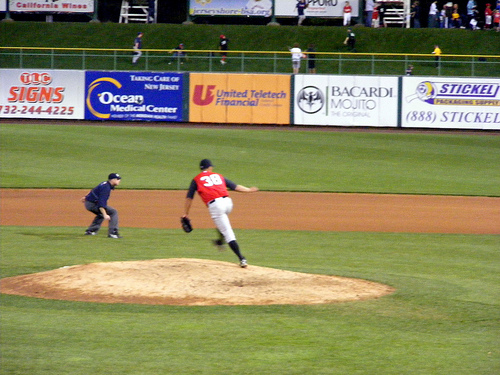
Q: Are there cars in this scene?
A: No, there are no cars.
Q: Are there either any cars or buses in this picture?
A: No, there are no cars or buses.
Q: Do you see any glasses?
A: No, there are no glasses.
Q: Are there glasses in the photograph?
A: No, there are no glasses.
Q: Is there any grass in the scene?
A: Yes, there is grass.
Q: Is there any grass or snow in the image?
A: Yes, there is grass.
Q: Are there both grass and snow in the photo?
A: No, there is grass but no snow.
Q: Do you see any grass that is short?
A: Yes, there is short grass.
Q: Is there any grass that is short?
A: Yes, there is grass that is short.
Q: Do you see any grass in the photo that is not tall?
A: Yes, there is short grass.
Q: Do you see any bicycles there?
A: No, there are no bicycles.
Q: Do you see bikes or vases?
A: No, there are no bikes or vases.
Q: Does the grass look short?
A: Yes, the grass is short.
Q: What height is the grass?
A: The grass is short.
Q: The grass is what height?
A: The grass is short.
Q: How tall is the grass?
A: The grass is short.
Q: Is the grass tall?
A: No, the grass is short.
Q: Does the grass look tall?
A: No, the grass is short.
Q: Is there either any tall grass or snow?
A: No, there is grass but it is short.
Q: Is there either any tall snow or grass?
A: No, there is grass but it is short.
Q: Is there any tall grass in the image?
A: No, there is grass but it is short.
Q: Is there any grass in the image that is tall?
A: No, there is grass but it is short.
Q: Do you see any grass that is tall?
A: No, there is grass but it is short.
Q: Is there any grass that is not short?
A: No, there is grass but it is short.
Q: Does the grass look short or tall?
A: The grass is short.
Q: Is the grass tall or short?
A: The grass is short.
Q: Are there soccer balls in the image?
A: No, there are no soccer balls.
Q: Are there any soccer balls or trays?
A: No, there are no soccer balls or trays.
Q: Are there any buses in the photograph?
A: No, there are no buses.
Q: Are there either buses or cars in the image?
A: No, there are no buses or cars.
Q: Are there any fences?
A: Yes, there is a fence.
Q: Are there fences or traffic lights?
A: Yes, there is a fence.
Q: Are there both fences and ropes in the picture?
A: No, there is a fence but no ropes.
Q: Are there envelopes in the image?
A: No, there are no envelopes.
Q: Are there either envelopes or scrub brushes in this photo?
A: No, there are no envelopes or scrub brushes.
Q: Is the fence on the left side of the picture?
A: Yes, the fence is on the left of the image.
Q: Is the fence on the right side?
A: No, the fence is on the left of the image.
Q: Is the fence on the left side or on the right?
A: The fence is on the left of the image.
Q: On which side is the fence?
A: The fence is on the left of the image.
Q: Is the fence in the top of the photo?
A: Yes, the fence is in the top of the image.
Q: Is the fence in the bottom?
A: No, the fence is in the top of the image.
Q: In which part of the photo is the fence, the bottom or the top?
A: The fence is in the top of the image.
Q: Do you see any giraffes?
A: No, there are no giraffes.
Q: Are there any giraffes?
A: No, there are no giraffes.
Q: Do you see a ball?
A: No, there are no balls.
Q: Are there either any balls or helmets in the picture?
A: No, there are no balls or helmets.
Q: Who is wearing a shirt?
A: The player is wearing a shirt.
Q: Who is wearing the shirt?
A: The player is wearing a shirt.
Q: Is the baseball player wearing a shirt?
A: Yes, the player is wearing a shirt.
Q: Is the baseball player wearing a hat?
A: No, the player is wearing a shirt.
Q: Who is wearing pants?
A: The player is wearing pants.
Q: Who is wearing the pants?
A: The player is wearing pants.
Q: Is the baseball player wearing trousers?
A: Yes, the player is wearing trousers.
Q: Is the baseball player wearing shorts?
A: No, the player is wearing trousers.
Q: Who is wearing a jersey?
A: The player is wearing a jersey.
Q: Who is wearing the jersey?
A: The player is wearing a jersey.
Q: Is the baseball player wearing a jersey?
A: Yes, the player is wearing a jersey.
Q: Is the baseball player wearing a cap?
A: No, the player is wearing a jersey.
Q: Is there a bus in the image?
A: No, there are no buses.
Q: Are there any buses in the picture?
A: No, there are no buses.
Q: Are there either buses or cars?
A: No, there are no buses or cars.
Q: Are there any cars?
A: No, there are no cars.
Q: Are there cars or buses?
A: No, there are no cars or buses.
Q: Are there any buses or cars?
A: No, there are no cars or buses.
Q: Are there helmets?
A: No, there are no helmets.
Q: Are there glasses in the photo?
A: No, there are no glasses.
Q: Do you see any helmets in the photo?
A: No, there are no helmets.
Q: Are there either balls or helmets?
A: No, there are no helmets or balls.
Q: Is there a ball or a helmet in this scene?
A: No, there are no helmets or balls.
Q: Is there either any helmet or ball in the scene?
A: No, there are no helmets or balls.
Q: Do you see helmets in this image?
A: No, there are no helmets.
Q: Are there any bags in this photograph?
A: No, there are no bags.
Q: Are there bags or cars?
A: No, there are no bags or cars.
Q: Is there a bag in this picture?
A: No, there are no bags.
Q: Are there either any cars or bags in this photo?
A: No, there are no bags or cars.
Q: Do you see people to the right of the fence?
A: Yes, there are people to the right of the fence.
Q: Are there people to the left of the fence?
A: No, the people are to the right of the fence.